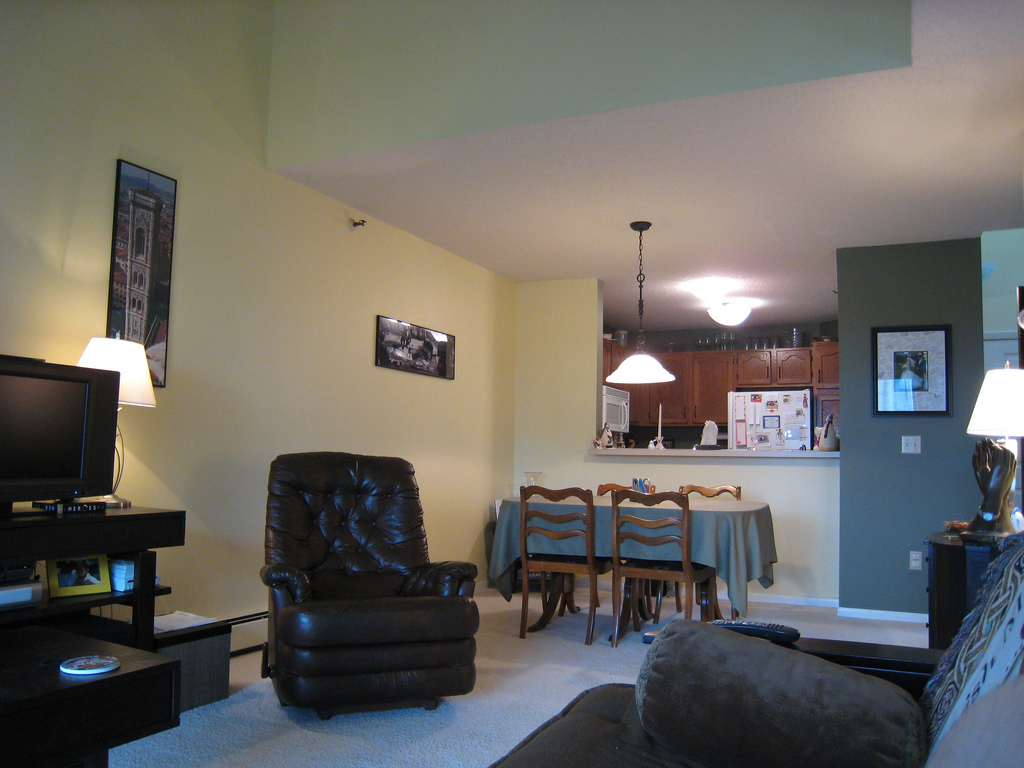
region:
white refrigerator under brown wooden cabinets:
[600, 339, 835, 450]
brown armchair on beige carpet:
[91, 449, 929, 763]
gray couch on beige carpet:
[100, 533, 1023, 767]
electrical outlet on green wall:
[837, 234, 987, 618]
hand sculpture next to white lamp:
[957, 354, 1022, 551]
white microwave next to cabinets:
[601, 341, 839, 434]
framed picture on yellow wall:
[2, 0, 516, 585]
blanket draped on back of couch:
[460, 531, 1023, 766]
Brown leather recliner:
[263, 449, 478, 716]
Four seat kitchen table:
[498, 483, 778, 642]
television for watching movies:
[3, 353, 118, 499]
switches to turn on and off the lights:
[903, 435, 923, 455]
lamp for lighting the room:
[73, 335, 153, 516]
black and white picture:
[376, 315, 462, 385]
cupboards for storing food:
[603, 341, 842, 428]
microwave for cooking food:
[600, 382, 633, 439]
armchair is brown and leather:
[258, 445, 486, 721]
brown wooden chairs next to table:
[477, 481, 787, 646]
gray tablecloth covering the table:
[482, 493, 784, 634]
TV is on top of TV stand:
[0, 354, 185, 659]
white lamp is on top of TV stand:
[2, 329, 190, 661]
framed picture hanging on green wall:
[834, 237, 984, 627]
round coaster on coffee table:
[0, 612, 187, 767]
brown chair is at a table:
[605, 488, 710, 641]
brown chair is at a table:
[513, 486, 615, 639]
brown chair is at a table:
[679, 483, 744, 502]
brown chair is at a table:
[595, 480, 656, 504]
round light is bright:
[605, 354, 673, 383]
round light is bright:
[71, 337, 154, 410]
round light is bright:
[961, 366, 1022, 442]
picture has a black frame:
[872, 327, 952, 414]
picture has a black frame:
[105, 158, 176, 397]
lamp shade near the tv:
[76, 314, 166, 420]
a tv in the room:
[0, 340, 128, 508]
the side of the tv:
[62, 349, 123, 496]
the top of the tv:
[2, 349, 119, 404]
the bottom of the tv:
[0, 469, 117, 507]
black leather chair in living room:
[241, 431, 529, 765]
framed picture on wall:
[81, 103, 195, 468]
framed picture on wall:
[351, 276, 508, 403]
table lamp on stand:
[57, 307, 185, 522]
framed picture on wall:
[854, 298, 984, 467]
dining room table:
[484, 453, 820, 628]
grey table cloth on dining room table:
[478, 452, 795, 646]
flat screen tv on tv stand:
[11, 336, 161, 518]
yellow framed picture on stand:
[26, 532, 170, 612]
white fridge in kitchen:
[712, 381, 842, 461]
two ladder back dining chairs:
[512, 481, 696, 652]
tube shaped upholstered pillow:
[629, 612, 928, 765]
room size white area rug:
[104, 601, 779, 764]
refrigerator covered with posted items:
[723, 384, 815, 452]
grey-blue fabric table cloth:
[480, 490, 782, 626]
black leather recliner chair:
[256, 444, 487, 723]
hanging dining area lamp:
[597, 215, 678, 389]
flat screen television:
[2, 349, 124, 512]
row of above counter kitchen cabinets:
[598, 337, 849, 427]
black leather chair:
[236, 433, 493, 718]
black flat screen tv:
[2, 351, 133, 519]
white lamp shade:
[71, 319, 167, 419]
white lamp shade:
[959, 354, 1021, 457]